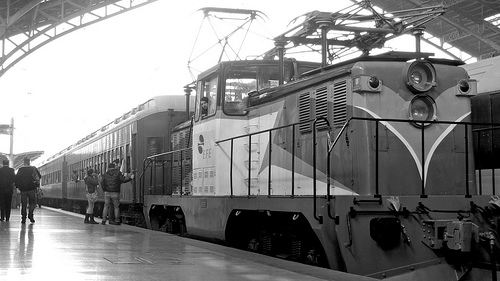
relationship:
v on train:
[364, 111, 479, 191] [181, 76, 470, 230]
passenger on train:
[202, 97, 214, 124] [181, 76, 470, 230]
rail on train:
[248, 126, 342, 186] [181, 76, 470, 230]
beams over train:
[99, 3, 385, 36] [181, 76, 470, 230]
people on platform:
[81, 162, 120, 194] [86, 233, 210, 278]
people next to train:
[81, 162, 120, 194] [181, 76, 470, 230]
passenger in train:
[202, 97, 214, 124] [181, 76, 470, 230]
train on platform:
[181, 76, 470, 230] [86, 233, 210, 278]